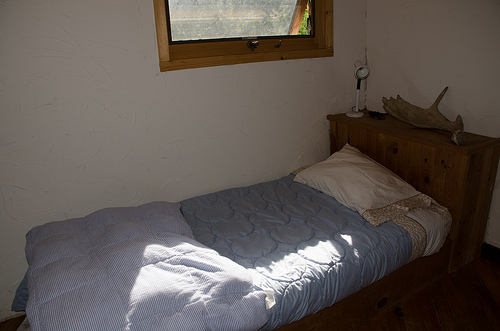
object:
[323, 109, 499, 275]
headboard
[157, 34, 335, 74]
frame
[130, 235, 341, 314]
light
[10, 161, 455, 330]
bed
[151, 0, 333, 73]
window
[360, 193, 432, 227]
leopard pattern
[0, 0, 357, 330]
wall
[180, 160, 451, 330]
bed-cover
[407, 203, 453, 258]
white sheet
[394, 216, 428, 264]
leopard pattern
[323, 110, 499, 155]
top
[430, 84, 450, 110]
branch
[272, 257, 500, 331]
floor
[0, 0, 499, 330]
room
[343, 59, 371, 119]
lamp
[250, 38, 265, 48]
handle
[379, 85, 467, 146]
antler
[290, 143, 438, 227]
pillow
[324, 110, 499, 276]
shelf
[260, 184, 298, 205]
circle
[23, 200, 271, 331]
blanket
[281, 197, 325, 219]
circle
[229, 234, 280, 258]
circle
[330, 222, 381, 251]
circle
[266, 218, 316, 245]
circle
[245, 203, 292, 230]
circle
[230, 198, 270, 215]
circle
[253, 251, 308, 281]
circle